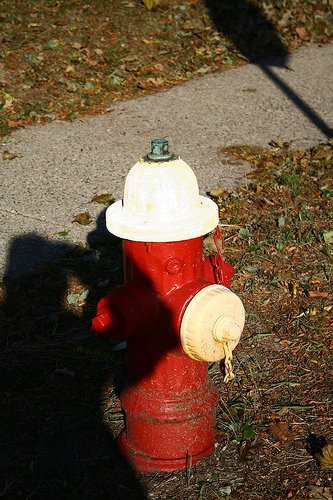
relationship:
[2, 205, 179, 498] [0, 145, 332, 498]
shadow on grass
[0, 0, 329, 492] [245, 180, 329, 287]
patch covered in grass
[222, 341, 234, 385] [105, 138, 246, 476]
chain from hydrant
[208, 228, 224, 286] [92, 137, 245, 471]
chain from hydrant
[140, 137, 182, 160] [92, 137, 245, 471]
top from hydrant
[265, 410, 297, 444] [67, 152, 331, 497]
leaf in grass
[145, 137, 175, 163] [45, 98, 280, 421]
top in hydrant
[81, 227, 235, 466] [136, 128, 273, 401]
bottom from hydrant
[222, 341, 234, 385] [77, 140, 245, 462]
chain hanging from hydrant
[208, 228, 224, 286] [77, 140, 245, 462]
chain hanging from hydrant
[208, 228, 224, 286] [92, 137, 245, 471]
chain hanging from hydrant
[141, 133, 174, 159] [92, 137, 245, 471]
bolt on top of hydrant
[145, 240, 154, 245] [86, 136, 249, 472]
bolt on fire hydrant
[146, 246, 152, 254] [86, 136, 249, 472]
screw on fire hydrant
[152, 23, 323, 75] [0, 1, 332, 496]
black shadow on ground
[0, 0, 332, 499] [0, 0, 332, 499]
patch on patch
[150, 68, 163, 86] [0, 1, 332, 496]
leaf on ground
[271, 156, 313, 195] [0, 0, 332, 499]
grass on patch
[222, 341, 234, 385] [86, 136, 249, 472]
chain hanging from fire hydrant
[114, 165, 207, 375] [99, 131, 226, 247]
hydrant with cap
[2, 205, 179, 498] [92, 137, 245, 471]
shadow behind hydrant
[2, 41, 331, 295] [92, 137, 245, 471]
sidewalk behind hydrant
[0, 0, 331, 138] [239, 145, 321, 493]
leaves on ground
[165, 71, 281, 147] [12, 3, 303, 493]
debris on ground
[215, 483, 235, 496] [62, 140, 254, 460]
rock by hydrant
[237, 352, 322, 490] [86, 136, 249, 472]
grass growing by fire hydrant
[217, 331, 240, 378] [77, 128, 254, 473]
chain hanging off hydrant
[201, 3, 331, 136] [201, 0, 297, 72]
shadow from sign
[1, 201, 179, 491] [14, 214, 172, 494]
person taking picture shadow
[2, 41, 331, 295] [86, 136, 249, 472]
sidewalk behind fire hydrant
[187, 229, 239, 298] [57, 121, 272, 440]
chain hanging from hydrant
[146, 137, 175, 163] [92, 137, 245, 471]
bolt on top of hydrant